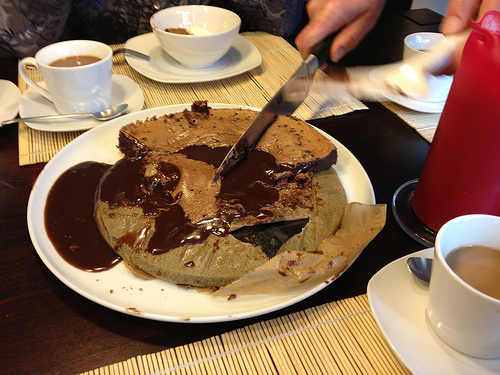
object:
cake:
[93, 101, 348, 289]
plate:
[26, 102, 378, 324]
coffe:
[48, 55, 103, 68]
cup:
[19, 39, 114, 116]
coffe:
[445, 242, 500, 299]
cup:
[426, 214, 500, 358]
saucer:
[17, 73, 147, 133]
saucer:
[366, 247, 498, 375]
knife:
[212, 35, 335, 184]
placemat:
[15, 27, 369, 168]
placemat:
[80, 293, 414, 374]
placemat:
[383, 97, 444, 143]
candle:
[411, 10, 499, 233]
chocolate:
[44, 148, 210, 273]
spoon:
[1, 103, 129, 125]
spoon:
[406, 257, 434, 284]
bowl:
[150, 5, 241, 69]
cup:
[403, 32, 452, 100]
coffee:
[418, 48, 431, 52]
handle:
[311, 34, 338, 67]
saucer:
[369, 60, 455, 114]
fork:
[112, 47, 149, 61]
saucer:
[123, 31, 264, 84]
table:
[0, 0, 499, 374]